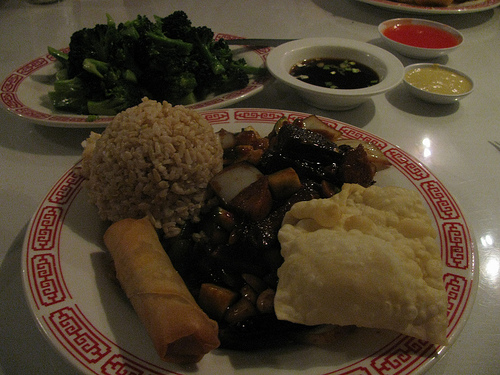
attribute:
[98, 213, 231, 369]
roll — brown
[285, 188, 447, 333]
wonton — puffy, fried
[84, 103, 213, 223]
rice — brown, fried rice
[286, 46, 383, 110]
sauce — brown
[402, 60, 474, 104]
sauce — yellow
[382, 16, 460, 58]
sauce — reddish, orange, pink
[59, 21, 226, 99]
broccoli — green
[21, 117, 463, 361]
plate — large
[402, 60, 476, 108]
bowl — white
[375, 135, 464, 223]
pattern — red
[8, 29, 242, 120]
plate — white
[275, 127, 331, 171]
rib — red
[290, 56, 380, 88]
sauce — sweet and sour